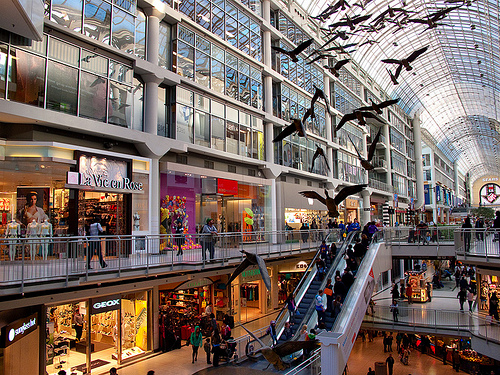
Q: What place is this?
A: It is a mall.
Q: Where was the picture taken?
A: It was taken at the mall.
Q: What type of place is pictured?
A: It is a mall.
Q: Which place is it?
A: It is a mall.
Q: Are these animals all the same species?
A: No, there are both geese and birds.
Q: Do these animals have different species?
A: Yes, they are geese and birds.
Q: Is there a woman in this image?
A: Yes, there is a woman.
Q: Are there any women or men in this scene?
A: Yes, there is a woman.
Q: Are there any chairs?
A: No, there are no chairs.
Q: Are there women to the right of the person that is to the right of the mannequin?
A: Yes, there is a woman to the right of the person.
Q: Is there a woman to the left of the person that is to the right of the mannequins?
A: No, the woman is to the right of the person.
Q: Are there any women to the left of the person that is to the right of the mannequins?
A: No, the woman is to the right of the person.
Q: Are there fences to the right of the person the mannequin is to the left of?
A: No, there is a woman to the right of the person.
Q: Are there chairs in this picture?
A: No, there are no chairs.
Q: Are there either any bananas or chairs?
A: No, there are no chairs or bananas.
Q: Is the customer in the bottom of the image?
A: Yes, the customer is in the bottom of the image.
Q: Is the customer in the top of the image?
A: No, the customer is in the bottom of the image.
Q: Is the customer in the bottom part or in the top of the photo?
A: The customer is in the bottom of the image.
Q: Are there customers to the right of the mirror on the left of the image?
A: Yes, there is a customer to the right of the mirror.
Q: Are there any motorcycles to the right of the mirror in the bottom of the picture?
A: No, there is a customer to the right of the mirror.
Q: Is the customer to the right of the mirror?
A: Yes, the customer is to the right of the mirror.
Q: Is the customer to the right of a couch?
A: No, the customer is to the right of the mirror.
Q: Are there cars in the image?
A: No, there are no cars.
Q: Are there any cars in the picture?
A: No, there are no cars.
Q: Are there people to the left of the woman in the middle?
A: Yes, there is a person to the left of the woman.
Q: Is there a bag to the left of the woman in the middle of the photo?
A: No, there is a person to the left of the woman.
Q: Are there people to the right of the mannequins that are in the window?
A: Yes, there is a person to the right of the mannequins.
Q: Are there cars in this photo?
A: No, there are no cars.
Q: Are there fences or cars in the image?
A: No, there are no cars or fences.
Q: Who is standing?
A: The people are standing.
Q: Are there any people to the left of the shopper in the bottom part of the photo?
A: Yes, there are people to the left of the shopper.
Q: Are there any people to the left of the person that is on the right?
A: Yes, there are people to the left of the shopper.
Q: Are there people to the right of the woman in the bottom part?
A: Yes, there are people to the right of the woman.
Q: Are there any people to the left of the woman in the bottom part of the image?
A: No, the people are to the right of the woman.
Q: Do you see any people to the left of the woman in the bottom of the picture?
A: No, the people are to the right of the woman.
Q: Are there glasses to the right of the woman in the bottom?
A: No, there are people to the right of the woman.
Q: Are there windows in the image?
A: Yes, there is a window.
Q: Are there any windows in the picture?
A: Yes, there is a window.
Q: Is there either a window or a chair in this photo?
A: Yes, there is a window.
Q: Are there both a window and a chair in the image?
A: No, there is a window but no chairs.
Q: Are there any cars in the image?
A: No, there are no cars.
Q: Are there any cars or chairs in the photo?
A: No, there are no cars or chairs.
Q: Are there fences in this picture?
A: No, there are no fences.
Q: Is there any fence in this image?
A: No, there are no fences.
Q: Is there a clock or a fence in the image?
A: No, there are no fences or clocks.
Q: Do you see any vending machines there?
A: No, there are no vending machines.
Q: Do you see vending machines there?
A: No, there are no vending machines.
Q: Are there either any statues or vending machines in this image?
A: No, there are no vending machines or statues.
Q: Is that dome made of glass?
A: Yes, the dome is made of glass.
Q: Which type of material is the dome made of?
A: The dome is made of glass.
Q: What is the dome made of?
A: The dome is made of glass.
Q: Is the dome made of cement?
A: No, the dome is made of glass.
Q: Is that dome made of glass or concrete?
A: The dome is made of glass.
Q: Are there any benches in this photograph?
A: No, there are no benches.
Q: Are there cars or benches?
A: No, there are no benches or cars.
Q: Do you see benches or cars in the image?
A: No, there are no benches or cars.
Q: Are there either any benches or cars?
A: No, there are no benches or cars.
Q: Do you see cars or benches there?
A: No, there are no benches or cars.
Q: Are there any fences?
A: No, there are no fences.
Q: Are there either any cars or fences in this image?
A: No, there are no fences or cars.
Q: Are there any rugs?
A: No, there are no rugs.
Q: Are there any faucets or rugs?
A: No, there are no rugs or faucets.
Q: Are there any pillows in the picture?
A: No, there are no pillows.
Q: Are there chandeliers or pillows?
A: No, there are no pillows or chandeliers.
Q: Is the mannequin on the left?
A: Yes, the mannequin is on the left of the image.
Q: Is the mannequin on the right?
A: No, the mannequin is on the left of the image.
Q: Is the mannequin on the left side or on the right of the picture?
A: The mannequin is on the left of the image.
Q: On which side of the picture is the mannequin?
A: The mannequin is on the left of the image.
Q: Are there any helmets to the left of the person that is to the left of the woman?
A: No, there is a mannequin to the left of the person.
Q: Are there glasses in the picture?
A: No, there are no glasses.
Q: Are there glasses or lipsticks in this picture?
A: No, there are no glasses or lipsticks.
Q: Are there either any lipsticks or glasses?
A: No, there are no glasses or lipsticks.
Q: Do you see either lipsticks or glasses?
A: No, there are no glasses or lipsticks.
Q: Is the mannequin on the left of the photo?
A: Yes, the mannequin is on the left of the image.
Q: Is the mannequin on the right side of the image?
A: No, the mannequin is on the left of the image.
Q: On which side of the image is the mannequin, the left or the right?
A: The mannequin is on the left of the image.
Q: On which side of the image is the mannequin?
A: The mannequin is on the left of the image.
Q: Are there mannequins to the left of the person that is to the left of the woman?
A: Yes, there is a mannequin to the left of the person.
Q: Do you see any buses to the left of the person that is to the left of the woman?
A: No, there is a mannequin to the left of the person.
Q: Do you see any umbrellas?
A: No, there are no umbrellas.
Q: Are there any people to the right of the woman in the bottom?
A: Yes, there are people to the right of the woman.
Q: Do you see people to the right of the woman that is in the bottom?
A: Yes, there are people to the right of the woman.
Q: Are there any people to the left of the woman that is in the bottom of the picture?
A: No, the people are to the right of the woman.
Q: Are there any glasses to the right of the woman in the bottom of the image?
A: No, there are people to the right of the woman.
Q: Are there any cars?
A: No, there are no cars.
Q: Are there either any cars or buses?
A: No, there are no cars or buses.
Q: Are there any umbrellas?
A: No, there are no umbrellas.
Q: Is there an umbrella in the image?
A: No, there are no umbrellas.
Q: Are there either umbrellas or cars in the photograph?
A: No, there are no umbrellas or cars.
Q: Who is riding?
A: The people are riding.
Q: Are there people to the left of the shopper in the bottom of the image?
A: Yes, there are people to the left of the shopper.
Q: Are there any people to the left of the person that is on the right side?
A: Yes, there are people to the left of the shopper.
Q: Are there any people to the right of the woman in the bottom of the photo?
A: Yes, there are people to the right of the woman.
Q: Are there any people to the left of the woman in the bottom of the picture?
A: No, the people are to the right of the woman.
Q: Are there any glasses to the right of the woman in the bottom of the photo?
A: No, there are people to the right of the woman.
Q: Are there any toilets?
A: No, there are no toilets.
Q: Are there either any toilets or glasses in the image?
A: No, there are no toilets or glasses.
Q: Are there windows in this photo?
A: Yes, there is a window.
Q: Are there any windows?
A: Yes, there is a window.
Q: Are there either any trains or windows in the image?
A: Yes, there is a window.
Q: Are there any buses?
A: No, there are no buses.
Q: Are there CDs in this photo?
A: No, there are no cds.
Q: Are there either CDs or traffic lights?
A: No, there are no CDs or traffic lights.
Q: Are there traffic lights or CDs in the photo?
A: No, there are no CDs or traffic lights.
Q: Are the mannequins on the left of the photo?
A: Yes, the mannequins are on the left of the image.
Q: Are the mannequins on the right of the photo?
A: No, the mannequins are on the left of the image.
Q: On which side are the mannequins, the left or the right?
A: The mannequins are on the left of the image.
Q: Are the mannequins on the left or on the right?
A: The mannequins are on the left of the image.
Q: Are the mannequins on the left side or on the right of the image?
A: The mannequins are on the left of the image.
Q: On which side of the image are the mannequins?
A: The mannequins are on the left of the image.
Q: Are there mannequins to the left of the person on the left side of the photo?
A: Yes, there are mannequins to the left of the person.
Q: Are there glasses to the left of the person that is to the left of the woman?
A: No, there are mannequins to the left of the person.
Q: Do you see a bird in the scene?
A: Yes, there is a bird.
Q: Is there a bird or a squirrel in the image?
A: Yes, there is a bird.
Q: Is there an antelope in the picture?
A: No, there are no antelopes.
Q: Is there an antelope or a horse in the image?
A: No, there are no antelopes or horses.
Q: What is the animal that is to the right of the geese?
A: The animal is a bird.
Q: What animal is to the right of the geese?
A: The animal is a bird.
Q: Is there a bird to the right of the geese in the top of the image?
A: Yes, there is a bird to the right of the geese.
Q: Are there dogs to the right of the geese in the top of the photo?
A: No, there is a bird to the right of the geese.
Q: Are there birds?
A: Yes, there is a bird.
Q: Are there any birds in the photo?
A: Yes, there is a bird.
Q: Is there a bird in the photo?
A: Yes, there is a bird.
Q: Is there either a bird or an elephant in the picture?
A: Yes, there is a bird.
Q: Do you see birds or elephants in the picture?
A: Yes, there is a bird.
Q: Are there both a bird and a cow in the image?
A: No, there is a bird but no cows.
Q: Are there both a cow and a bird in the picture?
A: No, there is a bird but no cows.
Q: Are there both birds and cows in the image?
A: No, there is a bird but no cows.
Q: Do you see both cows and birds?
A: No, there is a bird but no cows.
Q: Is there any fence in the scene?
A: No, there are no fences.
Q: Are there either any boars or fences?
A: No, there are no fences or boars.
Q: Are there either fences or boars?
A: No, there are no fences or boars.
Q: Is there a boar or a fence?
A: No, there are no fences or boars.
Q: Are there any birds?
A: Yes, there is a bird.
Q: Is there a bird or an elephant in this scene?
A: Yes, there is a bird.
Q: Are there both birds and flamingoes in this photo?
A: No, there is a bird but no flamingoes.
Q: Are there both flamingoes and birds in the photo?
A: No, there is a bird but no flamingoes.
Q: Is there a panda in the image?
A: No, there are no pandas.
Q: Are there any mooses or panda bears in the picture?
A: No, there are no panda bears or mooses.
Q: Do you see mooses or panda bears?
A: No, there are no panda bears or mooses.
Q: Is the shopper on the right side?
A: Yes, the shopper is on the right of the image.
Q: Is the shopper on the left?
A: No, the shopper is on the right of the image.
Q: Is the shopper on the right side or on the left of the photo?
A: The shopper is on the right of the image.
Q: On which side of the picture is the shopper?
A: The shopper is on the right of the image.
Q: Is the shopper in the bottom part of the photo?
A: Yes, the shopper is in the bottom of the image.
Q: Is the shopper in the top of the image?
A: No, the shopper is in the bottom of the image.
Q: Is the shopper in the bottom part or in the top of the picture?
A: The shopper is in the bottom of the image.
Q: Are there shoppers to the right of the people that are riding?
A: Yes, there is a shopper to the right of the people.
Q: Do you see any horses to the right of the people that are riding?
A: No, there is a shopper to the right of the people.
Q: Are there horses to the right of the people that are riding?
A: No, there is a shopper to the right of the people.